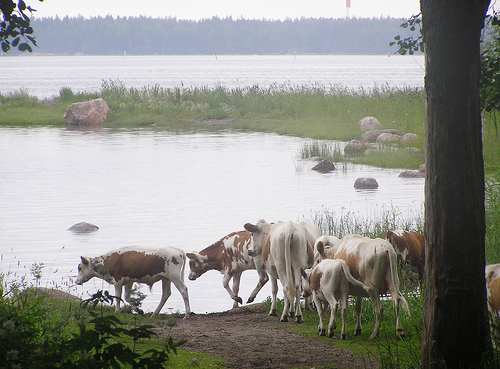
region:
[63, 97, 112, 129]
large rock in the grass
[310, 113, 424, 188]
large group of rock by water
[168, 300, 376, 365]
walkway to the water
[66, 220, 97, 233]
rock in the water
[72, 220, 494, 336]
family of cows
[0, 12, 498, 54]
trees on the shoreline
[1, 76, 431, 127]
tall green grass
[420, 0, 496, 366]
truck of a tall tree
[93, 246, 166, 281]
brown spots on the cow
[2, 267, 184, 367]
tall green plants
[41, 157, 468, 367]
several cows walking toward the water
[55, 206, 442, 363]
several cows walking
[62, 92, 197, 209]
a boulder on the edge of the water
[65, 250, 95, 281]
the head of a cow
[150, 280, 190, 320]
the rear legs of a cow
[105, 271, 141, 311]
the front legs of a cow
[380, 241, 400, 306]
the tail of a cow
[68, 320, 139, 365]
the leaves of a plant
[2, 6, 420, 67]
a line of trees along the water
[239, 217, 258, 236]
the ear of a cow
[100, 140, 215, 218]
Lake that is shimmering reflection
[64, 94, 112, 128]
Tan boulder rock close to lake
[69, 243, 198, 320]
White cow with brown spots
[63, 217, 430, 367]
Group of cows along the river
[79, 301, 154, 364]
Green shrubs along the pathway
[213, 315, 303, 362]
Dark pathway for animals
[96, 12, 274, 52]
Background of trees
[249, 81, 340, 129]
Green weeds along the river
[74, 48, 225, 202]
Two lake beds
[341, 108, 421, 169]
Pile of brown rocks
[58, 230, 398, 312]
These are a group of cows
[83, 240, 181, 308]
The cow is brown and white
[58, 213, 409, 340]
The cows are walking towards the water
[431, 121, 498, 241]
This is a tree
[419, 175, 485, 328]
This is tree bark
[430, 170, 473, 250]
The tree bark is brown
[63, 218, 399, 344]
The cows are going to drink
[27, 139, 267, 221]
This is a pond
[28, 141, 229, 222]
The water is white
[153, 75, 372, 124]
This is tall grass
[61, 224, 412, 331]
goats walking along pond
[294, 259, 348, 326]
calf walking with cows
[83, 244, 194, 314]
first cow in line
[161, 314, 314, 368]
dirt path leading to pond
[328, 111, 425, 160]
rock pile next to pond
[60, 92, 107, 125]
large rock on other side of pond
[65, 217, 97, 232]
rock in middle of pond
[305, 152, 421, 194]
rocks in water's edge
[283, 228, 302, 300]
white tail of cow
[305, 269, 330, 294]
brown spot on white calf